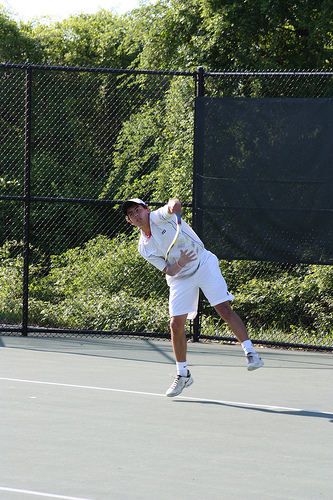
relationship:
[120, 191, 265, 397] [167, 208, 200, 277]
man holding racket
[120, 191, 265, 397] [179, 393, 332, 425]
man has shadow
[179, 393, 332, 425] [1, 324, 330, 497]
shadow on top of court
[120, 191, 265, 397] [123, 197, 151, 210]
man wearing cap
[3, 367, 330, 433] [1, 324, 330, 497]
lines on top of court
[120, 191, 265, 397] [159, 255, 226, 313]
man wearing shorts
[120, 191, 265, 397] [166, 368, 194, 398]
man with right foot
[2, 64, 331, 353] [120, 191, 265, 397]
fence behind man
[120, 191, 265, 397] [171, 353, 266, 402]
man wearing sneakers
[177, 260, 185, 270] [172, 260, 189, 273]
wristband around right wrist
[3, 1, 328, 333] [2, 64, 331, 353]
trees behind fence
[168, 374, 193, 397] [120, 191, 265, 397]
right foot of man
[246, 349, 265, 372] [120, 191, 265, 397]
left foot of man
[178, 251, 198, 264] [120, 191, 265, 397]
right hand of man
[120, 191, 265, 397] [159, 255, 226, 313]
man in shorts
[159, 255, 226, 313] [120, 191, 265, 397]
shorts on body of man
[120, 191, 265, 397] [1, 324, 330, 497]
man playing on court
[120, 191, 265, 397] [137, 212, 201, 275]
man wearing shirt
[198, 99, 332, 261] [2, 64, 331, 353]
fabric hanging on fence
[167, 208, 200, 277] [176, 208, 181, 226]
racket has handle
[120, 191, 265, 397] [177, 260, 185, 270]
man wearing wristband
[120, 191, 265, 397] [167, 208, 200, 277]
man swinging racket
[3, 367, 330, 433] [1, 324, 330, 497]
lines painted on court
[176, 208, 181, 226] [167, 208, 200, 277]
handle of racket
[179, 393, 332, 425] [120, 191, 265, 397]
shadow of man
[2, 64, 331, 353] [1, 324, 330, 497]
fence around court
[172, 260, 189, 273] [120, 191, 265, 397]
right wrist of man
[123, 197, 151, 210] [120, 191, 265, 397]
cap on head of man